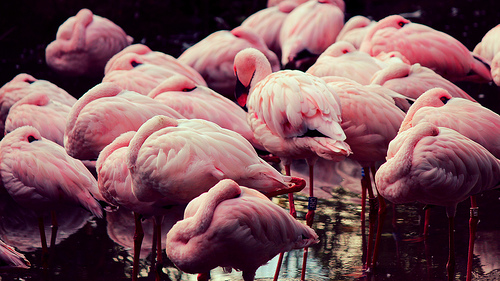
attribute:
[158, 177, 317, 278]
flamingoe — sleeping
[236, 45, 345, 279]
bird — standing , sleeping 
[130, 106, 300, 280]
bird — standing , sleeping 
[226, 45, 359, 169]
flamingo — pink, resting, sleeping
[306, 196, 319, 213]
tag — blue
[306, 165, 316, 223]
leg — orange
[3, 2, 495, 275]
flamingoes — pink, standing , sleeping